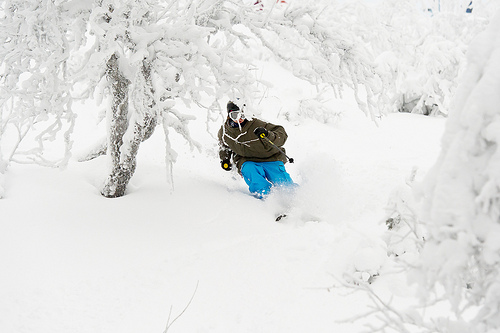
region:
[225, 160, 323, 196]
Blue snowboarding pants.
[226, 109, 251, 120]
Goggles to protect eyes.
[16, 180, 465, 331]
Soft snow covering the ground.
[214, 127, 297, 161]
Brown winter coat.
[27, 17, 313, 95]
Warm knit hat.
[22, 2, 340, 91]
Snow covering the branches.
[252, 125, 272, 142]
Gloves on his hands.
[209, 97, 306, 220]
Skier in the snow.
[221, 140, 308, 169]
Skier using ski poles.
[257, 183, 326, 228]
Skier kicking up snow into the air.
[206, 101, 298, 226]
a man skiing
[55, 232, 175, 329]
the snow on the ground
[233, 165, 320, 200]
the man's blue pants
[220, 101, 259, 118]
the man with the helmet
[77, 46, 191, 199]
trees with snow on it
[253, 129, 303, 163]
ski poles held by man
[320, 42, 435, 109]
snow in the back ground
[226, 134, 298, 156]
jacket of the skiier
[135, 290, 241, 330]
branch in foreground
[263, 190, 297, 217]
snow flying in front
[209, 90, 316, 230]
A man skiing in the snow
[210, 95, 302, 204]
A skier wearing blue pants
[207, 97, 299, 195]
A skier wearing a dark green jacket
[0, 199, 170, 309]
Clean, untouched snow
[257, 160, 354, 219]
A cloud of kicked-up snow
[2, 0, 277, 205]
A snowy tree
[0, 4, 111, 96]
Snow-covered branches of a tree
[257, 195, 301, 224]
The tip of a ski emerging from the snow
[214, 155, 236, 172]
The yellow handle of a ski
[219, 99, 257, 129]
A man wearing a protective mask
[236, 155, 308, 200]
blue snow pant on a man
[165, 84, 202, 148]
snowy branches of a tree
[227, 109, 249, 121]
a person wearing snow goggles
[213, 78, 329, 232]
a person skiing down a hill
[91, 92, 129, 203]
tree trunk with snow on it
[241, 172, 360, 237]
spray of snow from skis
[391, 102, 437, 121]
tree trunks at the edge of the snow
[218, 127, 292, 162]
person wearing a winter coat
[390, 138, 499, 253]
a tree covered with snow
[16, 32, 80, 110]
tree branches covered with snow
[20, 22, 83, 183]
curly branches covered in snow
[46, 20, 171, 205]
tree trunk split in two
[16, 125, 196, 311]
snow covering ground in wooded area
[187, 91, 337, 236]
skier going down slope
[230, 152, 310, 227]
skier wearing baggy blue pants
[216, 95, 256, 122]
skier in large white goggles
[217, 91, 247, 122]
skier wearing a pointy black hat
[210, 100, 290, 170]
skier wearing a puffy brown jacket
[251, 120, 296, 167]
pole in skier's hand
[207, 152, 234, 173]
yellow end of ski pole in skier's grip